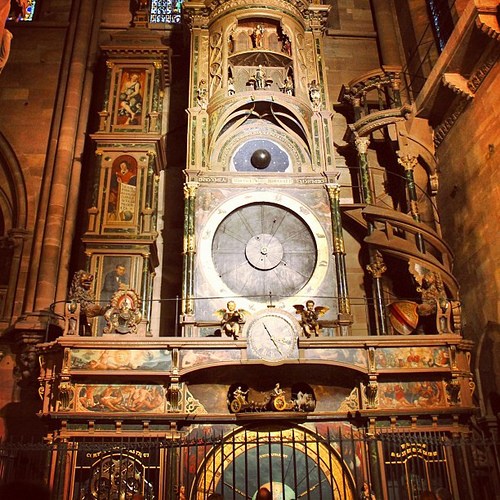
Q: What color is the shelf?
A: Brown.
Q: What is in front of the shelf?
A: Gate.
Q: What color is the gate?
A: Black.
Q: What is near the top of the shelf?
A: Window.